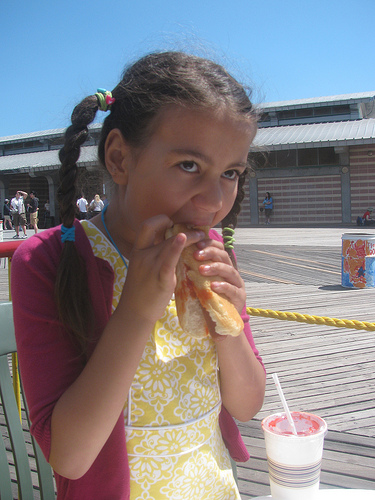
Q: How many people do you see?
A: More than six.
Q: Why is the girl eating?
A: Hunger.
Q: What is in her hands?
A: Hot Dog.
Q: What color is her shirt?
A: Yellow.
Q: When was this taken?
A: Daytime.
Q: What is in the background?
A: People.